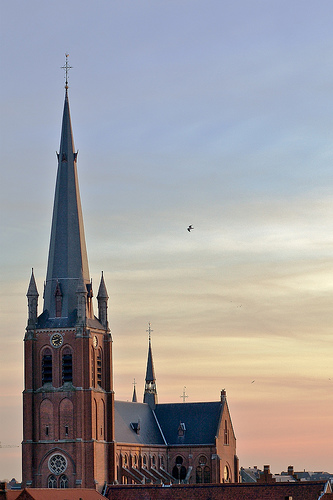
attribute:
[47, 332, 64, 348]
clock — steeple , tower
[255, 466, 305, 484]
chimneys — brick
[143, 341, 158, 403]
steeple — lower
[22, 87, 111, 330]
roof — highest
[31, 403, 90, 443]
windows — small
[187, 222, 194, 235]
bird — in the air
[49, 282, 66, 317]
design — round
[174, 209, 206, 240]
bird — flying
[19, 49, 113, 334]
tower — brick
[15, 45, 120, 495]
building — tall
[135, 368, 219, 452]
rooftops — tiled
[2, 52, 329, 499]
building — brick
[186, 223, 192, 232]
bird — small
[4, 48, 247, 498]
building — stone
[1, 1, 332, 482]
clouds — white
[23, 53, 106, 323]
steeple — tall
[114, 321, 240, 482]
building — lower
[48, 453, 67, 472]
window — round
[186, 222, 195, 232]
bird — flying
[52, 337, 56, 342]
hand — big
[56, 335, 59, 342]
hand — small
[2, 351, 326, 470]
bands — pink